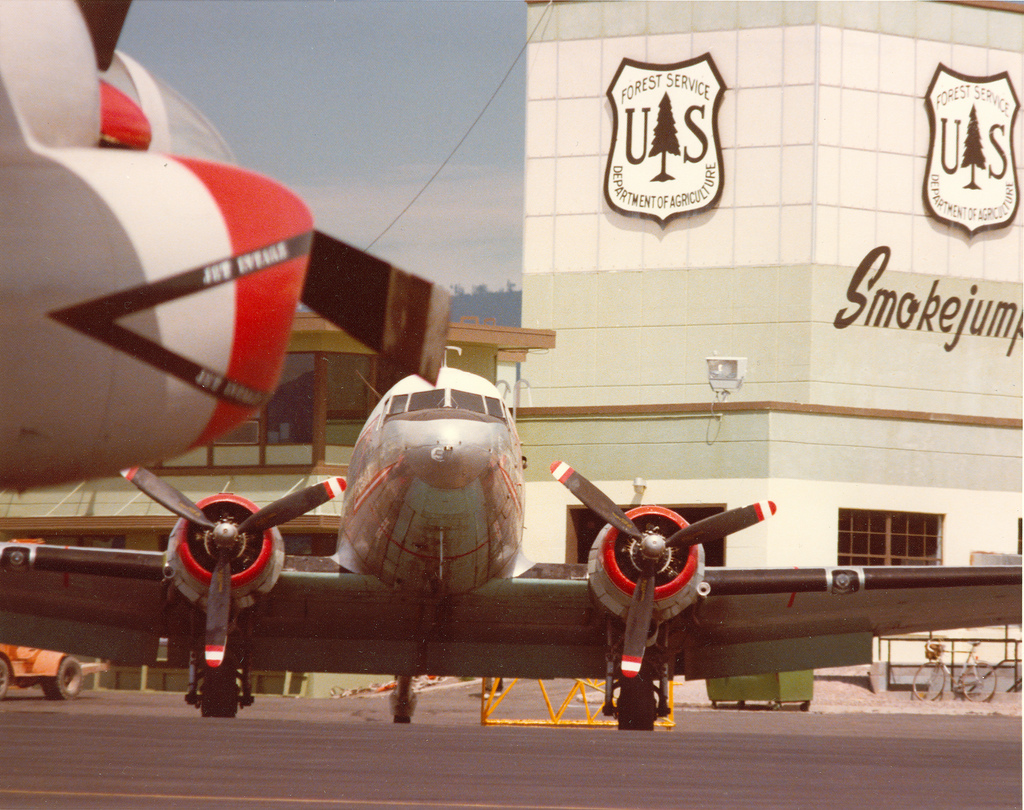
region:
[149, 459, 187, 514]
propeller on the plane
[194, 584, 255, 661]
propeller on the plane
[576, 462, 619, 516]
propeller on the plane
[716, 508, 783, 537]
propeller on the plane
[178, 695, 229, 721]
wheel on the plane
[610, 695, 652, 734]
wheel on the plane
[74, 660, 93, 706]
wheel on the plane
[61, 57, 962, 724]
this is an airport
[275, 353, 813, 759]
the plane is white and silver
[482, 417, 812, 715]
this is a propeller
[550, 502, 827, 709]
the engine is red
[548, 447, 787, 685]
An engine on the plane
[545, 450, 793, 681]
A propeller on a plane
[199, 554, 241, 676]
A blade on a propeller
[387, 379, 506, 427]
Windows on an airplane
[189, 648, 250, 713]
A wheel on an airplane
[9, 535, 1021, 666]
Wings on a plane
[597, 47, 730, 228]
A sign on a building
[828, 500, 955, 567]
Windows on a building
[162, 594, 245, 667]
propeller on the plane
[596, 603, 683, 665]
propeller on the plane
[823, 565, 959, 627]
wing of the plane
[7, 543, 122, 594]
wing of the plane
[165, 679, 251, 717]
heel of the plane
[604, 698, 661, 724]
wheel of the plane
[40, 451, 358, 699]
right propeller on a plane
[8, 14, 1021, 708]
building is the airport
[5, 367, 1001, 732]
plane is parked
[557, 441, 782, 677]
propeller is black with red and white striped tips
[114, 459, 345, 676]
propeller is black with red and white striped tips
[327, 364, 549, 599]
cockpit of the airplane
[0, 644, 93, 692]
vehicle is parked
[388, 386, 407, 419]
a window on a plane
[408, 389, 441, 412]
a window on a plane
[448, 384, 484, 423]
a window on a plane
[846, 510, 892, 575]
a window on a building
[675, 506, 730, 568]
a window on a building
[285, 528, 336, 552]
a window on a building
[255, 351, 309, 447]
a window on a building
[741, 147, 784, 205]
wall panel is white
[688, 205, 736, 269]
wall panel is white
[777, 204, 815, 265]
wall panel is white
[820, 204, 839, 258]
wall panel is white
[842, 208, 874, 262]
wall panel is white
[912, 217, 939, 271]
wall panel is white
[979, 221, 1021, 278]
wall panel is white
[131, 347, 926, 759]
white plane in airport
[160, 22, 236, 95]
white clouds in blue sky